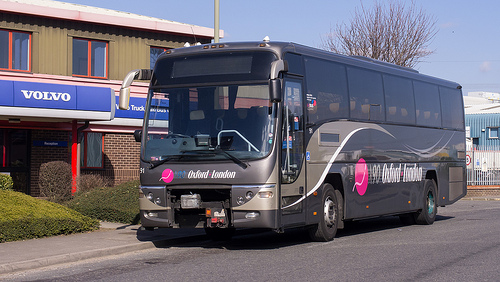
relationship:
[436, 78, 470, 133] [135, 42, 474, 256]
window on bus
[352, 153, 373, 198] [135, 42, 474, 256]
logo on bus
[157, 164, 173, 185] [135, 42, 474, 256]
logo on bus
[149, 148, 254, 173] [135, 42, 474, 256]
windshield wipers are on bus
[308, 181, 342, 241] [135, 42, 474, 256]
tire on bus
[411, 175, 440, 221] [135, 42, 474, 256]
tire on bus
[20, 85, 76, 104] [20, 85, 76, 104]
logo on logo